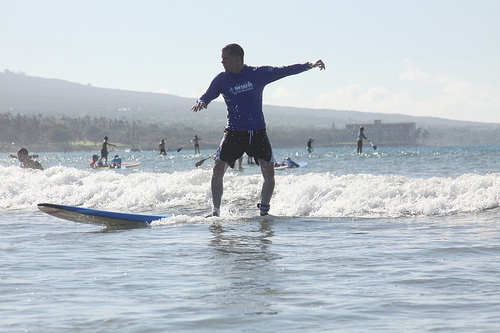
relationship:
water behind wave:
[0, 147, 499, 332] [0, 157, 499, 230]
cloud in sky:
[328, 66, 497, 96] [0, 2, 496, 114]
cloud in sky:
[18, 16, 217, 63] [0, 2, 496, 114]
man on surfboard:
[188, 35, 333, 219] [33, 198, 170, 230]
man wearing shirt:
[188, 35, 333, 219] [198, 62, 312, 126]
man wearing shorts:
[188, 35, 333, 219] [218, 130, 273, 168]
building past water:
[342, 117, 422, 147] [1, 143, 498, 331]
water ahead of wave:
[2, 212, 499, 331] [2, 157, 496, 216]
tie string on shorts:
[245, 127, 255, 141] [221, 129, 272, 163]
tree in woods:
[49, 110, 89, 152] [2, 110, 104, 137]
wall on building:
[346, 123, 416, 145] [345, 120, 416, 144]